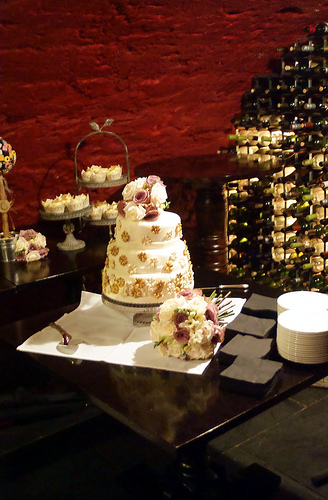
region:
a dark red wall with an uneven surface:
[1, 1, 325, 244]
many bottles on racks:
[216, 22, 326, 290]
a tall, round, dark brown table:
[133, 153, 286, 272]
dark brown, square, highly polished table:
[3, 263, 326, 499]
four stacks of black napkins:
[219, 286, 282, 397]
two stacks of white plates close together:
[275, 290, 326, 365]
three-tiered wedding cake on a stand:
[99, 209, 195, 323]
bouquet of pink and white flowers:
[149, 288, 235, 359]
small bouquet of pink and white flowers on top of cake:
[102, 174, 197, 304]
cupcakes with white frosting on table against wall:
[0, 93, 130, 317]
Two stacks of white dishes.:
[277, 288, 326, 376]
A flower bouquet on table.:
[155, 289, 238, 365]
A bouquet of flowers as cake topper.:
[114, 174, 173, 218]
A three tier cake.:
[103, 212, 191, 300]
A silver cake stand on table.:
[99, 296, 172, 332]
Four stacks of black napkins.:
[218, 287, 280, 398]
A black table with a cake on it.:
[8, 174, 325, 496]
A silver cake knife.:
[196, 284, 252, 293]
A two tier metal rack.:
[73, 119, 136, 238]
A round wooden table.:
[131, 152, 288, 271]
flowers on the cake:
[123, 182, 166, 211]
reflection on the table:
[120, 373, 203, 415]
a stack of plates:
[277, 313, 325, 364]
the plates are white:
[275, 319, 327, 362]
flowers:
[150, 300, 217, 360]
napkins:
[226, 362, 275, 385]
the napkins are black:
[218, 364, 277, 391]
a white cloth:
[94, 314, 133, 358]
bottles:
[238, 195, 280, 269]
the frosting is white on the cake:
[115, 234, 184, 291]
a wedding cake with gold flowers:
[105, 173, 193, 304]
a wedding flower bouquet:
[152, 290, 235, 360]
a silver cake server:
[49, 322, 75, 347]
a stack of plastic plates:
[276, 307, 327, 365]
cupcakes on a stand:
[40, 192, 92, 251]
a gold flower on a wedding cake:
[118, 254, 127, 265]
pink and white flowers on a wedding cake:
[117, 176, 169, 221]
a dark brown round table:
[137, 152, 265, 277]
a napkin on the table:
[221, 354, 283, 385]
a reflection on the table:
[110, 361, 189, 441]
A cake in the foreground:
[96, 167, 195, 323]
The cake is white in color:
[95, 167, 202, 318]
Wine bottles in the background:
[216, 11, 326, 292]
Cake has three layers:
[86, 169, 207, 324]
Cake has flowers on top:
[116, 169, 173, 228]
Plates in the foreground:
[261, 282, 325, 373]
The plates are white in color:
[261, 282, 325, 371]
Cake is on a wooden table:
[3, 171, 326, 468]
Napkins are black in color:
[207, 288, 289, 401]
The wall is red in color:
[1, 3, 327, 234]